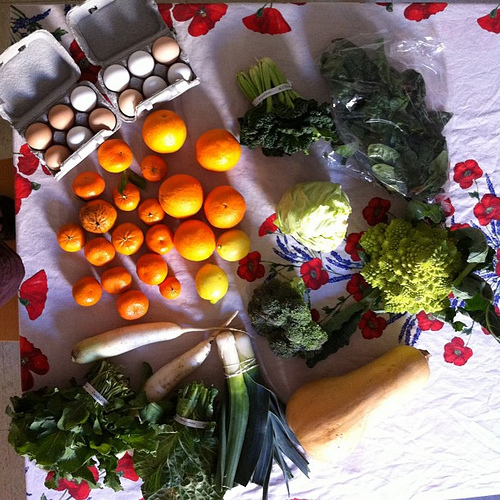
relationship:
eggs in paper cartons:
[6, 35, 211, 166] [3, 4, 145, 132]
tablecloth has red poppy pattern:
[5, 4, 494, 493] [170, 6, 498, 51]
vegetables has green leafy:
[253, 28, 483, 458] [10, 363, 246, 497]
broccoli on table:
[244, 268, 334, 369] [5, 4, 494, 493]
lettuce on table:
[298, 21, 469, 226] [5, 4, 494, 493]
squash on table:
[352, 206, 473, 331] [5, 4, 494, 493]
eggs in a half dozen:
[6, 35, 211, 166] [98, 34, 197, 111]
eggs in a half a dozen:
[6, 35, 211, 166] [19, 83, 120, 184]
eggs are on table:
[6, 35, 211, 166] [5, 4, 494, 493]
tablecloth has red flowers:
[5, 4, 494, 493] [239, 6, 302, 43]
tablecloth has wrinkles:
[5, 4, 494, 493] [450, 32, 497, 160]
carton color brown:
[8, 31, 212, 184] [23, 100, 68, 167]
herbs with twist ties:
[222, 50, 329, 159] [249, 78, 294, 108]